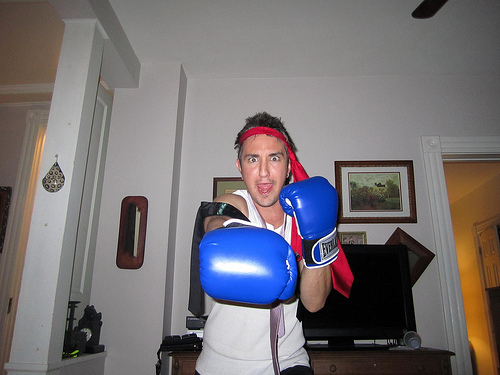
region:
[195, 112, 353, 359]
Man in boxing gloves acting out.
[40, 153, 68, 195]
Sandy color wall hanging with circles.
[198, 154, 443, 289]
Several pictures and frame hanging on wall.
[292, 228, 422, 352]
Large black screen television.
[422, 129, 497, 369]
Hall way with white molding.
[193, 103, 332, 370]
Man with red head tie.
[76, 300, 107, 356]
Clock hidden in the corner.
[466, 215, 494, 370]
Door in hallway slightly ajar.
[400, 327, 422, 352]
Water bottle on its side.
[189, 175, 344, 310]
Blue boxing gloves with writing.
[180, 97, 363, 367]
This is a person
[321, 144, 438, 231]
Picture on the wall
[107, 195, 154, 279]
Handle on the wall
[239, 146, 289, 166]
Eyes of a person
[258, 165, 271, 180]
Nose of a person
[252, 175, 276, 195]
Mouth of a person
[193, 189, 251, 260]
Hand of a person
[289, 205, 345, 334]
Hand of a person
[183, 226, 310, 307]
This is boxing gear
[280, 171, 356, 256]
This is boxing gear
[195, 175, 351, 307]
man wearing large blue boxing gloves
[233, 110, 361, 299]
bright red tie tied around man's head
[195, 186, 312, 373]
man wearing a loose white undershirt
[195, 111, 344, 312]
man is holding his gloved right hand away from his body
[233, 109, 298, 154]
man's hair appears disheveled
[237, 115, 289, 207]
man's eyes are wide open and his mouth is open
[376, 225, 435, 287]
frame on wall is askew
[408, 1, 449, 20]
the dark blade of a ceiling fan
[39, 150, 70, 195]
teardrop-shaped decorative item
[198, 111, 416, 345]
flat screen television behind man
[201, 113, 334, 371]
man standing in room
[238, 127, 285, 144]
red tie around forehead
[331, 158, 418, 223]
picture in brown frame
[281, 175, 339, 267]
blue boxing glove with label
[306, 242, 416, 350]
black flat screen television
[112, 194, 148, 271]
long rectangle wall decoration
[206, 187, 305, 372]
long white tank top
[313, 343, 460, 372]
wood table against wall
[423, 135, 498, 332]
doorway with white frame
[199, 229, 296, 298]
top of blue boxing glove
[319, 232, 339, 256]
Black letters on boxing glove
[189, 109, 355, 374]
Man wearing blue boxing gloves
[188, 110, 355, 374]
Man wearing red tie on head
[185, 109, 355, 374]
Man wearing black tie around arm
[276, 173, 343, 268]
Blue and white and black boxing gloves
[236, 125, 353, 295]
Red tie around head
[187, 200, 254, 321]
Black tie around arm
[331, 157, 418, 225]
Rectangle shaped picture on wall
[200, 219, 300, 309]
Blue and white and black boxing glove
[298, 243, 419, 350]
Black television